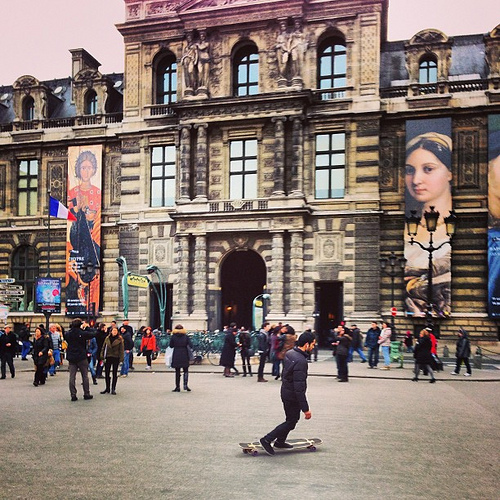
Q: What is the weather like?
A: It is overcast.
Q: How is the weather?
A: It is overcast.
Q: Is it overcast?
A: Yes, it is overcast.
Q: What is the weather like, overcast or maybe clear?
A: It is overcast.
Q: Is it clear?
A: No, it is overcast.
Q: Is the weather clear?
A: No, it is overcast.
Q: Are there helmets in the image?
A: No, there are no helmets.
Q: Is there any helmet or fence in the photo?
A: No, there are no helmets or fences.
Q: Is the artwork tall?
A: Yes, the artwork is tall.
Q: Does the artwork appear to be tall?
A: Yes, the artwork is tall.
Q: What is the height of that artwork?
A: The artwork is tall.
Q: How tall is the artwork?
A: The artwork is tall.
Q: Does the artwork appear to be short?
A: No, the artwork is tall.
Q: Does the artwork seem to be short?
A: No, the artwork is tall.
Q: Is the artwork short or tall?
A: The artwork is tall.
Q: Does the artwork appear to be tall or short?
A: The artwork is tall.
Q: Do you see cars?
A: No, there are no cars.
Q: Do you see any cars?
A: No, there are no cars.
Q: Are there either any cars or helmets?
A: No, there are no cars or helmets.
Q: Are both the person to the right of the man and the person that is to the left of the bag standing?
A: Yes, both the person and the person are standing.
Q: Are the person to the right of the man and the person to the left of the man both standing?
A: Yes, both the person and the person are standing.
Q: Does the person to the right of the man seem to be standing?
A: Yes, the person is standing.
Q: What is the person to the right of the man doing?
A: The person is standing.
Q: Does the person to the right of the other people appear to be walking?
A: No, the person is standing.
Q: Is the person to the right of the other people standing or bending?
A: The person is standing.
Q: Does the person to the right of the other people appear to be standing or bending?
A: The person is standing.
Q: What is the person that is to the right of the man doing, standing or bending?
A: The person is standing.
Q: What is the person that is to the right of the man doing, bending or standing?
A: The person is standing.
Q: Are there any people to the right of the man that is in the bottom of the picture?
A: Yes, there is a person to the right of the man.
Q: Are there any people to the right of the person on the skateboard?
A: Yes, there is a person to the right of the man.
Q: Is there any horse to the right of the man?
A: No, there is a person to the right of the man.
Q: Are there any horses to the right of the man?
A: No, there is a person to the right of the man.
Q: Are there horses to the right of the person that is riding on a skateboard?
A: No, there is a person to the right of the man.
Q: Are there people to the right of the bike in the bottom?
A: Yes, there is a person to the right of the bike.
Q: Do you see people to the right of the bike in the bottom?
A: Yes, there is a person to the right of the bike.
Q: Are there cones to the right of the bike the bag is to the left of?
A: No, there is a person to the right of the bike.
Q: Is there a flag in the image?
A: Yes, there is a flag.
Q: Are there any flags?
A: Yes, there is a flag.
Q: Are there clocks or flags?
A: Yes, there is a flag.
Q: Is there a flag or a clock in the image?
A: Yes, there is a flag.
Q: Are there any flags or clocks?
A: Yes, there is a flag.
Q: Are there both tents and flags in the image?
A: No, there is a flag but no tents.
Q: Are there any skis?
A: No, there are no skis.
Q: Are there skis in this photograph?
A: No, there are no skis.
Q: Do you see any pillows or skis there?
A: No, there are no skis or pillows.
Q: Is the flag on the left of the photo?
A: Yes, the flag is on the left of the image.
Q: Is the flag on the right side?
A: No, the flag is on the left of the image.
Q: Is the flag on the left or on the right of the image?
A: The flag is on the left of the image.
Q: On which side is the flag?
A: The flag is on the left of the image.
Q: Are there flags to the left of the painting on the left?
A: Yes, there is a flag to the left of the painting.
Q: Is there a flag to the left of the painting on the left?
A: Yes, there is a flag to the left of the painting.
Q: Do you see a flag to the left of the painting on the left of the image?
A: Yes, there is a flag to the left of the painting.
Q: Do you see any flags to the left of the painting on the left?
A: Yes, there is a flag to the left of the painting.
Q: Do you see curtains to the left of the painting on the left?
A: No, there is a flag to the left of the painting.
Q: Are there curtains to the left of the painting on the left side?
A: No, there is a flag to the left of the painting.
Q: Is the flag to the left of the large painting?
A: Yes, the flag is to the left of the painting.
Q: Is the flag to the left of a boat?
A: No, the flag is to the left of the painting.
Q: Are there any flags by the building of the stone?
A: Yes, there is a flag by the building.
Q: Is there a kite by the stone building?
A: No, there is a flag by the building.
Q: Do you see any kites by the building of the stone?
A: No, there is a flag by the building.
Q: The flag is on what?
A: The flag is on the pole.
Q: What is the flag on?
A: The flag is on the pole.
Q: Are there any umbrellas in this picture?
A: No, there are no umbrellas.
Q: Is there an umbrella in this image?
A: No, there are no umbrellas.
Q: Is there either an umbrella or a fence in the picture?
A: No, there are no umbrellas or fences.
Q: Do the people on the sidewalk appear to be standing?
A: Yes, the people are standing.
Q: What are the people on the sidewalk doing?
A: The people are standing.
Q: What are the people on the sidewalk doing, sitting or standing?
A: The people are standing.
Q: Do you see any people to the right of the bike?
A: Yes, there are people to the right of the bike.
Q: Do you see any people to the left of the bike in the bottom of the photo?
A: No, the people are to the right of the bike.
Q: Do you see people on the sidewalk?
A: Yes, there are people on the sidewalk.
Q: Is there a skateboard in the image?
A: Yes, there is a skateboard.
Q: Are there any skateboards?
A: Yes, there is a skateboard.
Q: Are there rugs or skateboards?
A: Yes, there is a skateboard.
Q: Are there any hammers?
A: No, there are no hammers.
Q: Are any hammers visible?
A: No, there are no hammers.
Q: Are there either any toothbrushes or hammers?
A: No, there are no hammers or toothbrushes.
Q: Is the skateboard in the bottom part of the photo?
A: Yes, the skateboard is in the bottom of the image.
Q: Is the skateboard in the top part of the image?
A: No, the skateboard is in the bottom of the image.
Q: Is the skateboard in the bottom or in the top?
A: The skateboard is in the bottom of the image.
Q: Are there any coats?
A: Yes, there is a coat.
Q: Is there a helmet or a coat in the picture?
A: Yes, there is a coat.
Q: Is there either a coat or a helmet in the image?
A: Yes, there is a coat.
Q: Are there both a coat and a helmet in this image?
A: No, there is a coat but no helmets.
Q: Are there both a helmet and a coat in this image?
A: No, there is a coat but no helmets.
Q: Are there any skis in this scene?
A: No, there are no skis.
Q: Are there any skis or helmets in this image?
A: No, there are no skis or helmets.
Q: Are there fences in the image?
A: No, there are no fences.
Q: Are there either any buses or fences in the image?
A: No, there are no fences or buses.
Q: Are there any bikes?
A: Yes, there is a bike.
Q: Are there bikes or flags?
A: Yes, there is a bike.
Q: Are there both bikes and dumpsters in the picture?
A: No, there is a bike but no dumpsters.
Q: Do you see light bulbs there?
A: No, there are no light bulbs.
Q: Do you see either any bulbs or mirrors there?
A: No, there are no bulbs or mirrors.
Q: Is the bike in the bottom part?
A: Yes, the bike is in the bottom of the image.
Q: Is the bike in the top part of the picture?
A: No, the bike is in the bottom of the image.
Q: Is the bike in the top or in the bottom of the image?
A: The bike is in the bottom of the image.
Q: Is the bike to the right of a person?
A: Yes, the bike is to the right of a person.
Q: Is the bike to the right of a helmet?
A: No, the bike is to the right of a person.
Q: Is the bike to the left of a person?
A: Yes, the bike is to the left of a person.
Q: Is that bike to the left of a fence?
A: No, the bike is to the left of a person.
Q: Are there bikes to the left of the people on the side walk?
A: Yes, there is a bike to the left of the people.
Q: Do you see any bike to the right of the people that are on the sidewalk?
A: No, the bike is to the left of the people.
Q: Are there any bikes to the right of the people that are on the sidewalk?
A: No, the bike is to the left of the people.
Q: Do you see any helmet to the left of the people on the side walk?
A: No, there is a bike to the left of the people.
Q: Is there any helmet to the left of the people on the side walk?
A: No, there is a bike to the left of the people.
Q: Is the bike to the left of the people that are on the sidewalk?
A: Yes, the bike is to the left of the people.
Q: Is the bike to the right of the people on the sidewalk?
A: No, the bike is to the left of the people.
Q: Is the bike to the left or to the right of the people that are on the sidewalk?
A: The bike is to the left of the people.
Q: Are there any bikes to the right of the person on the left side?
A: Yes, there is a bike to the right of the person.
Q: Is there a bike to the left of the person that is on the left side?
A: No, the bike is to the right of the person.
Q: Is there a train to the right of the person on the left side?
A: No, there is a bike to the right of the person.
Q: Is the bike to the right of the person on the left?
A: Yes, the bike is to the right of the person.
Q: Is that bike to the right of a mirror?
A: No, the bike is to the right of the person.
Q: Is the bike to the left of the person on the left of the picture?
A: No, the bike is to the right of the person.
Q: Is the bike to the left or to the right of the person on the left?
A: The bike is to the right of the person.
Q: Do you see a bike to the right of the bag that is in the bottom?
A: Yes, there is a bike to the right of the bag.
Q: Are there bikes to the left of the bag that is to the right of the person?
A: No, the bike is to the right of the bag.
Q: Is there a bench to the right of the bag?
A: No, there is a bike to the right of the bag.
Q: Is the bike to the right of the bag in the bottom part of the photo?
A: Yes, the bike is to the right of the bag.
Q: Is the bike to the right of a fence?
A: No, the bike is to the right of the bag.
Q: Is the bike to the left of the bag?
A: No, the bike is to the right of the bag.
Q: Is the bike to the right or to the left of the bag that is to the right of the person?
A: The bike is to the right of the bag.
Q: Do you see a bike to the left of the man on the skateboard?
A: Yes, there is a bike to the left of the man.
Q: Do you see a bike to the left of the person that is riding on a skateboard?
A: Yes, there is a bike to the left of the man.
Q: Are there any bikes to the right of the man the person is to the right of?
A: No, the bike is to the left of the man.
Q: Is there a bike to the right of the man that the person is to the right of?
A: No, the bike is to the left of the man.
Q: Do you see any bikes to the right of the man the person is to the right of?
A: No, the bike is to the left of the man.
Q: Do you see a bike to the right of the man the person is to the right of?
A: No, the bike is to the left of the man.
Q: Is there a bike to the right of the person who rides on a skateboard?
A: No, the bike is to the left of the man.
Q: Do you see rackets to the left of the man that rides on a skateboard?
A: No, there is a bike to the left of the man.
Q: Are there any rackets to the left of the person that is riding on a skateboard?
A: No, there is a bike to the left of the man.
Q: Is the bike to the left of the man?
A: Yes, the bike is to the left of the man.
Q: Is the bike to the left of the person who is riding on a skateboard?
A: Yes, the bike is to the left of the man.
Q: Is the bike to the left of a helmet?
A: No, the bike is to the left of the man.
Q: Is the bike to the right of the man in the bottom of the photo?
A: No, the bike is to the left of the man.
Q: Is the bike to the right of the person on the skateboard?
A: No, the bike is to the left of the man.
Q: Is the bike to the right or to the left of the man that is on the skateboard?
A: The bike is to the left of the man.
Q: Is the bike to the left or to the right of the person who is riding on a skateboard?
A: The bike is to the left of the man.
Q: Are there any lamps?
A: Yes, there is a lamp.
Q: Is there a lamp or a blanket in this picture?
A: Yes, there is a lamp.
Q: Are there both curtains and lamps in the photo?
A: No, there is a lamp but no curtains.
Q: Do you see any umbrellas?
A: No, there are no umbrellas.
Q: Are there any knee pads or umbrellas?
A: No, there are no umbrellas or knee pads.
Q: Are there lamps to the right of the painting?
A: Yes, there is a lamp to the right of the painting.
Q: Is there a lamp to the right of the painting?
A: Yes, there is a lamp to the right of the painting.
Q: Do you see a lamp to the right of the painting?
A: Yes, there is a lamp to the right of the painting.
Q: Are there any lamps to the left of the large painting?
A: No, the lamp is to the right of the painting.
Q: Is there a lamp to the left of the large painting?
A: No, the lamp is to the right of the painting.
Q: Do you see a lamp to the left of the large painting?
A: No, the lamp is to the right of the painting.